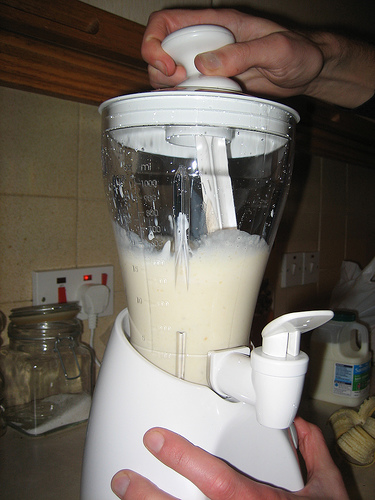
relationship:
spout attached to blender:
[253, 306, 293, 424] [95, 16, 293, 461]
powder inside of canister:
[31, 402, 94, 435] [2, 274, 92, 436]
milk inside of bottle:
[316, 381, 352, 400] [304, 305, 370, 408]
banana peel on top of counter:
[333, 411, 365, 461] [19, 460, 52, 474]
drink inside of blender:
[115, 225, 271, 394] [95, 16, 293, 461]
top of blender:
[104, 48, 284, 132] [95, 16, 293, 461]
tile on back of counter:
[0, 197, 76, 300] [0, 394, 375, 500]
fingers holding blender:
[132, 12, 264, 78] [95, 16, 293, 461]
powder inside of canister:
[47, 402, 83, 415] [0, 300, 96, 440]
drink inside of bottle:
[115, 225, 271, 394] [304, 305, 370, 408]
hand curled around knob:
[122, 13, 322, 88] [132, 12, 264, 78]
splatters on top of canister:
[68, 136, 189, 207] [0, 300, 96, 440]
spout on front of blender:
[253, 306, 293, 424] [95, 16, 293, 461]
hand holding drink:
[122, 13, 322, 88] [115, 225, 271, 394]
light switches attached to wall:
[282, 256, 320, 288] [321, 184, 353, 204]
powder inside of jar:
[31, 402, 94, 435] [2, 274, 92, 436]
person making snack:
[142, 5, 366, 117] [151, 262, 270, 333]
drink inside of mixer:
[115, 225, 271, 394] [95, 16, 293, 461]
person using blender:
[142, 5, 366, 117] [95, 16, 293, 461]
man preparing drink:
[142, 5, 366, 117] [95, 242, 229, 339]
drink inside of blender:
[95, 242, 229, 339] [95, 16, 293, 461]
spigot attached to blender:
[204, 351, 250, 401] [95, 16, 293, 461]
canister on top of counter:
[0, 300, 96, 440] [19, 460, 52, 474]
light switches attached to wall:
[282, 250, 302, 289] [321, 184, 353, 204]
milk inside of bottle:
[316, 381, 352, 400] [338, 401, 370, 411]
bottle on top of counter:
[338, 401, 370, 411] [19, 460, 52, 474]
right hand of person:
[132, 12, 264, 78] [111, 5, 375, 500]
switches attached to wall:
[290, 262, 324, 291] [321, 184, 353, 204]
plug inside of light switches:
[84, 293, 102, 306] [282, 250, 302, 289]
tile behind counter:
[8, 153, 90, 195] [19, 460, 52, 474]